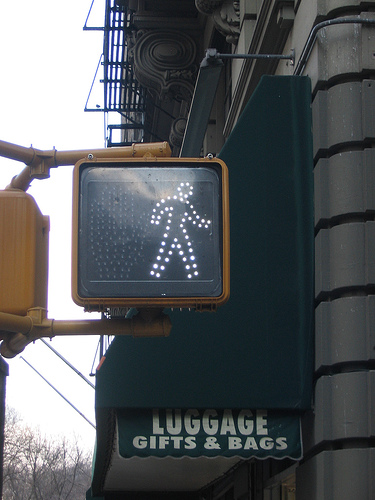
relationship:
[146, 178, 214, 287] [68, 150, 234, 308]
person on a sign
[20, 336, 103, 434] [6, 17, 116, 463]
wires in the sky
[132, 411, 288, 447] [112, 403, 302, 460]
writing on the sign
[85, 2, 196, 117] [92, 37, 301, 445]
ledge above the sign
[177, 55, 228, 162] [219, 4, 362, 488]
light hanging from the building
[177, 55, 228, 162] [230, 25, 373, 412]
light on building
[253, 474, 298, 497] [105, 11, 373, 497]
window in building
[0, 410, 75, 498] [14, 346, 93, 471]
trees in background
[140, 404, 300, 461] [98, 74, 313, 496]
letters in awning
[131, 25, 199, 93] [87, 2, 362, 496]
work on building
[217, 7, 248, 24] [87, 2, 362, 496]
leaf on building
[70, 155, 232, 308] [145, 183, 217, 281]
signage with bulbs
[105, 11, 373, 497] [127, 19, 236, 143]
building with sandstone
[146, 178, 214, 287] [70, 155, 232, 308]
person on signage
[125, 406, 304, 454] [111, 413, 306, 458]
letters on sign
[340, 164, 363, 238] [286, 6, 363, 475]
wall cladding of a building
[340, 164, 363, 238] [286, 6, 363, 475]
wall siding of a building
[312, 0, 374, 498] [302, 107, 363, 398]
wall siding of a building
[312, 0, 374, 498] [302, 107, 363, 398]
wall cladding  of a building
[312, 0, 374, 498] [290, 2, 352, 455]
wall cladding  of a building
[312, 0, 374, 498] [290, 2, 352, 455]
wall siding  of a building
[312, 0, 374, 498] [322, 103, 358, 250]
wall siding  of a building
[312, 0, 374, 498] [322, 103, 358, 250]
wall cladding  of a building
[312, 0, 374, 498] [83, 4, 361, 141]
wall cladding  of a building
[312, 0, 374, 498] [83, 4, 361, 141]
wall siding   of a building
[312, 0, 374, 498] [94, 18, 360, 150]
wall cladding  of a building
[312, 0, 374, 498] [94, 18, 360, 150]
wall siding   of a building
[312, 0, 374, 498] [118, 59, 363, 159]
wall cladding  of a building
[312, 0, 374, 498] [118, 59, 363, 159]
wall siding   of a building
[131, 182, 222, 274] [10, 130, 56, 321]
signage on a post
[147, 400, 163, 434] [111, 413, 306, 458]
letter on the sign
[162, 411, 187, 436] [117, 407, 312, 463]
letter on sign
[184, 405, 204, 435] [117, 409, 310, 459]
letter on sign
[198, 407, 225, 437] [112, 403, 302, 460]
letter on sign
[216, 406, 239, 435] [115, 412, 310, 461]
letter on sign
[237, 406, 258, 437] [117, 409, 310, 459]
letter on sign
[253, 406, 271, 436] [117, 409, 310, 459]
letter on sign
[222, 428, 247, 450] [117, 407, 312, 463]
letter on sign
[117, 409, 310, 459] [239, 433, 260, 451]
sign on letter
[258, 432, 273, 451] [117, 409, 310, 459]
letter on sign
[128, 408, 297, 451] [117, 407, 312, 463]
letters are on sign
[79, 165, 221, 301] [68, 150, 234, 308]
lights are on sign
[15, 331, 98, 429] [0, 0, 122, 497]
power cables are against sky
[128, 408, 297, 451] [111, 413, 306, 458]
letters are on sign